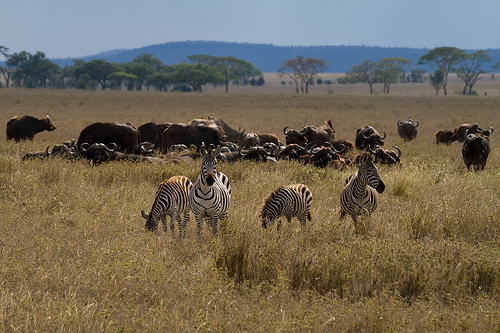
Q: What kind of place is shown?
A: It is a field.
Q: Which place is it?
A: It is a field.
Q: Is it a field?
A: Yes, it is a field.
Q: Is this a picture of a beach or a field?
A: It is showing a field.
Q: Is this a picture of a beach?
A: No, the picture is showing a field.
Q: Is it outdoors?
A: Yes, it is outdoors.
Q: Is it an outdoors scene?
A: Yes, it is outdoors.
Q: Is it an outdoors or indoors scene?
A: It is outdoors.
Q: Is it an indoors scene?
A: No, it is outdoors.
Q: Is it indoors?
A: No, it is outdoors.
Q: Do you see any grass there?
A: Yes, there is grass.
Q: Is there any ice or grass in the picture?
A: Yes, there is grass.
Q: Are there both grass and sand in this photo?
A: No, there is grass but no sand.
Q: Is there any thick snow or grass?
A: Yes, there is thick grass.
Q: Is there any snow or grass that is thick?
A: Yes, the grass is thick.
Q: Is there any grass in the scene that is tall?
A: Yes, there is tall grass.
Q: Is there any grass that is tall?
A: Yes, there is grass that is tall.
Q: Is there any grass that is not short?
A: Yes, there is tall grass.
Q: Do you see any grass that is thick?
A: Yes, there is thick grass.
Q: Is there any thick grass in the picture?
A: Yes, there is thick grass.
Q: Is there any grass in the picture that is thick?
A: Yes, there is grass that is thick.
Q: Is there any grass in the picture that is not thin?
A: Yes, there is thick grass.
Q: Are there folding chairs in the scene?
A: No, there are no folding chairs.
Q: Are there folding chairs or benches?
A: No, there are no folding chairs or benches.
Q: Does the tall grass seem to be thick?
A: Yes, the grass is thick.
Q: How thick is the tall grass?
A: The grass is thick.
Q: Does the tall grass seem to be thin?
A: No, the grass is thick.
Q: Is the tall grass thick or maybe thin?
A: The grass is thick.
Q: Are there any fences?
A: No, there are no fences.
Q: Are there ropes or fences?
A: No, there are no fences or ropes.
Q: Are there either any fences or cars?
A: No, there are no cars or fences.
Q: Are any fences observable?
A: No, there are no fences.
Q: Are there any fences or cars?
A: No, there are no fences or cars.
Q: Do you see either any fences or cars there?
A: No, there are no fences or cars.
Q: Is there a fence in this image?
A: No, there are no fences.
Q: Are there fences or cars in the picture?
A: No, there are no fences or cars.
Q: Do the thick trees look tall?
A: Yes, the trees are tall.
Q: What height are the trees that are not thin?
A: The trees are tall.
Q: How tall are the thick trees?
A: The trees are tall.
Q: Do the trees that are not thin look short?
A: No, the trees are tall.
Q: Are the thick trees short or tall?
A: The trees are tall.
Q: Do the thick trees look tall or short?
A: The trees are tall.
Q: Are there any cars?
A: No, there are no cars.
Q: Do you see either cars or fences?
A: No, there are no cars or fences.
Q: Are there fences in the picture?
A: No, there are no fences.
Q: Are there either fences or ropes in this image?
A: No, there are no fences or ropes.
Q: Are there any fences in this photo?
A: No, there are no fences.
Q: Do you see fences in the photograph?
A: No, there are no fences.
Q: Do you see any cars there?
A: No, there are no cars.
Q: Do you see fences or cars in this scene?
A: No, there are no cars or fences.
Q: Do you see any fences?
A: No, there are no fences.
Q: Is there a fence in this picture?
A: No, there are no fences.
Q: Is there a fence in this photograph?
A: No, there are no fences.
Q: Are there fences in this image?
A: No, there are no fences.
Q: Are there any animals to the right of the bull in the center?
A: Yes, there is an animal to the right of the bull.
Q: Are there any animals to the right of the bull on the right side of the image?
A: Yes, there is an animal to the right of the bull.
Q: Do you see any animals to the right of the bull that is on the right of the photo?
A: Yes, there is an animal to the right of the bull.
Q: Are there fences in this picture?
A: No, there are no fences.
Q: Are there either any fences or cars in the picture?
A: No, there are no fences or cars.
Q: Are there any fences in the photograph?
A: No, there are no fences.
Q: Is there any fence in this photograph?
A: No, there are no fences.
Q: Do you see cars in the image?
A: No, there are no cars.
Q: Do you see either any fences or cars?
A: No, there are no cars or fences.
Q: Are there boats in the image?
A: No, there are no boats.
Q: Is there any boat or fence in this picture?
A: No, there are no boats or fences.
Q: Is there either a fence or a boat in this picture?
A: No, there are no boats or fences.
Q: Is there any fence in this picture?
A: No, there are no fences.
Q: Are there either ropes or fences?
A: No, there are no fences or ropes.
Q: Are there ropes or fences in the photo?
A: No, there are no fences or ropes.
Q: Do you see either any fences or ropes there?
A: No, there are no fences or ropes.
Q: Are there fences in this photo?
A: No, there are no fences.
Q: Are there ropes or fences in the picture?
A: No, there are no fences or ropes.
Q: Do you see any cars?
A: No, there are no cars.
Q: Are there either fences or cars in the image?
A: No, there are no cars or fences.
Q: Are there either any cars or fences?
A: No, there are no cars or fences.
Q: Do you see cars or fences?
A: No, there are no cars or fences.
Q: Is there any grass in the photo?
A: Yes, there is grass.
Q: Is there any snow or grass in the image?
A: Yes, there is grass.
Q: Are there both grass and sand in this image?
A: No, there is grass but no sand.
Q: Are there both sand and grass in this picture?
A: No, there is grass but no sand.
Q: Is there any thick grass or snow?
A: Yes, there is thick grass.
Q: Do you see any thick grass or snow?
A: Yes, there is thick grass.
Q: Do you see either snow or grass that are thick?
A: Yes, the grass is thick.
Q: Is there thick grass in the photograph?
A: Yes, there is thick grass.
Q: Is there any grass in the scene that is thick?
A: Yes, there is grass that is thick.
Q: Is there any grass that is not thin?
A: Yes, there is thick grass.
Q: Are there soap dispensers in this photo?
A: No, there are no soap dispensers.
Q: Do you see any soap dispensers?
A: No, there are no soap dispensers.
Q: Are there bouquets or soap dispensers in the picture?
A: No, there are no soap dispensers or bouquets.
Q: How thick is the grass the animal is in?
A: The grass is thick.